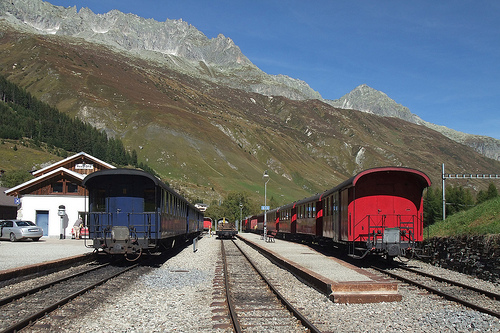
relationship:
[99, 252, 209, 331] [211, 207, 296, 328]
pebbles between tracks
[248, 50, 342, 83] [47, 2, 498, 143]
cloud in sky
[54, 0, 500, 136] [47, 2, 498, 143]
cloud in sky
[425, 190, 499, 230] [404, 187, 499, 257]
grass on slope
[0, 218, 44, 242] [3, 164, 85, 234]
car parked near building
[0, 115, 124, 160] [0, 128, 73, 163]
trees on slope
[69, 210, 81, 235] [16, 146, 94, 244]
person near building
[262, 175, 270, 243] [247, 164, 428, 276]
pole near train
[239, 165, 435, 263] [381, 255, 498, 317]
passenger train on track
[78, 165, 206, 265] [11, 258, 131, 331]
blue train on track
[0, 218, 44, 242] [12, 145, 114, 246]
car parked by building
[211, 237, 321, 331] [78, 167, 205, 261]
track by train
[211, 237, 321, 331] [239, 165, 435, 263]
track by passenger train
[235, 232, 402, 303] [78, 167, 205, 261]
median by train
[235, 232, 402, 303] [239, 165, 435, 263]
median by passenger train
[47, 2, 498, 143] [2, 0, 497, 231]
sky over mountains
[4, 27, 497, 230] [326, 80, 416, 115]
slope under mountaintop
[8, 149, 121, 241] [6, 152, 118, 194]
building with roofs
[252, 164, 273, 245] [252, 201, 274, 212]
pole with sign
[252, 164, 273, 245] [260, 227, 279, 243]
pole next to bench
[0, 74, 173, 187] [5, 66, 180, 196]
trees along a slope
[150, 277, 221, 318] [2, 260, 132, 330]
gravel between tracks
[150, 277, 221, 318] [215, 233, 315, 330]
gravel between tracks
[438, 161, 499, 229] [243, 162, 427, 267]
lights beside trains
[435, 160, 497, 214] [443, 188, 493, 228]
structure on hill